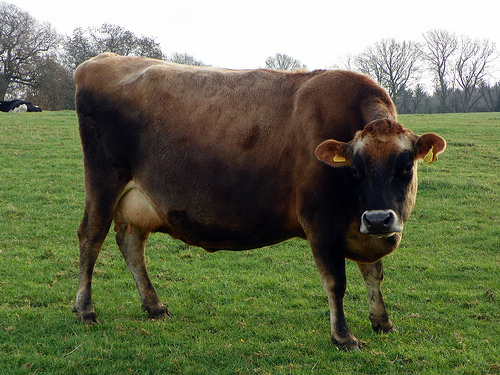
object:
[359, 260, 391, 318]
leg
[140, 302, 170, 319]
hoof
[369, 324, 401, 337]
hoof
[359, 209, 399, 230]
nose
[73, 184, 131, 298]
leg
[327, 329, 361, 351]
foot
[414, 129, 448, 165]
ear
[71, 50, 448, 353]
cow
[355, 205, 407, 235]
snout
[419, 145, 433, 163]
tag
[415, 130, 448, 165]
cows ear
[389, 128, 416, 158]
spots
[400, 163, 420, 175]
cows eyes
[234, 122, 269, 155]
spots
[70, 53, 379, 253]
cows side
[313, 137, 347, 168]
cows ear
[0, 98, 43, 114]
car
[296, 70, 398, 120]
hump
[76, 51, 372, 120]
cows back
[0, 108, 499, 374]
grass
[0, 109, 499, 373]
field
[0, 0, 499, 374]
outside scene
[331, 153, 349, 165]
tag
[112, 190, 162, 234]
utters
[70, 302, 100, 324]
hooves